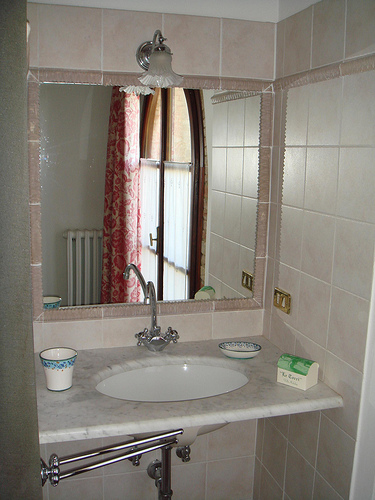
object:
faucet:
[135, 281, 180, 352]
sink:
[94, 354, 252, 403]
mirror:
[39, 80, 261, 308]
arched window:
[137, 86, 206, 301]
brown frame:
[136, 90, 215, 300]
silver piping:
[42, 438, 181, 499]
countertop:
[36, 347, 340, 445]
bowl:
[217, 340, 263, 360]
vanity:
[31, 306, 342, 408]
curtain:
[140, 158, 191, 303]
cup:
[39, 346, 78, 391]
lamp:
[137, 51, 184, 89]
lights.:
[273, 287, 291, 314]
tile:
[333, 145, 374, 231]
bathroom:
[3, 3, 371, 498]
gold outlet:
[273, 286, 291, 314]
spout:
[144, 281, 157, 327]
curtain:
[100, 86, 142, 304]